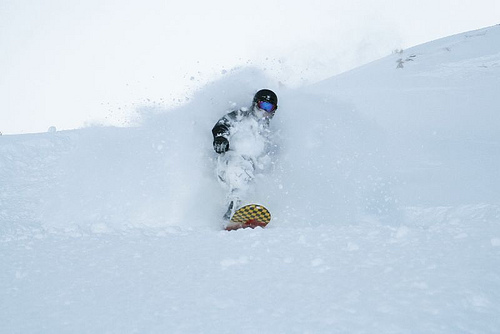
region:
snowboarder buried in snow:
[200, 70, 312, 239]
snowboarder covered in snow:
[209, 80, 288, 237]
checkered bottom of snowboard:
[226, 202, 275, 232]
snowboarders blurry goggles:
[256, 95, 276, 112]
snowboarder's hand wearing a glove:
[211, 133, 233, 158]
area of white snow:
[3, 57, 176, 332]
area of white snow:
[333, 75, 487, 279]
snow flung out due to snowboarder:
[116, 81, 206, 209]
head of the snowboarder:
[250, 82, 280, 119]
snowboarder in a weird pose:
[201, 74, 288, 234]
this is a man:
[186, 82, 301, 254]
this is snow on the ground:
[337, 228, 414, 273]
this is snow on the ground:
[158, 243, 231, 308]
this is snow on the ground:
[21, 183, 124, 295]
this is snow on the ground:
[314, 119, 385, 213]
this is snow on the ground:
[403, 203, 464, 288]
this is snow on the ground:
[46, 230, 110, 315]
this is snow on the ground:
[160, 260, 209, 320]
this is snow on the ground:
[359, 79, 421, 127]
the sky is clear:
[32, 34, 252, 79]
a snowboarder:
[199, 91, 291, 233]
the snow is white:
[9, 135, 169, 295]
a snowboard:
[234, 199, 275, 227]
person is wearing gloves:
[214, 138, 229, 157]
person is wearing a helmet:
[258, 88, 277, 99]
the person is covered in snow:
[227, 118, 267, 164]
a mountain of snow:
[419, 33, 497, 104]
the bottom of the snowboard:
[237, 208, 265, 219]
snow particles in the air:
[172, 66, 233, 96]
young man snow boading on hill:
[209, 85, 299, 240]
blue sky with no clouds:
[6, 7, 81, 58]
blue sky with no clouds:
[3, 47, 83, 105]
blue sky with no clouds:
[81, 53, 165, 81]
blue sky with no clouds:
[109, 10, 193, 56]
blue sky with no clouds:
[216, 17, 293, 39]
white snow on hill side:
[16, 147, 103, 209]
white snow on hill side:
[3, 242, 170, 331]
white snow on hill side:
[187, 268, 294, 304]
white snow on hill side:
[332, 127, 480, 259]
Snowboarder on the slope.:
[203, 84, 286, 228]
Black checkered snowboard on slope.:
[227, 200, 273, 228]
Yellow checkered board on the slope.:
[226, 203, 271, 229]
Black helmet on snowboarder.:
[248, 88, 280, 115]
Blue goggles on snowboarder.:
[255, 101, 277, 112]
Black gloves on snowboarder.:
[213, 135, 228, 155]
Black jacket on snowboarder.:
[208, 108, 273, 158]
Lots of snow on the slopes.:
[3, 20, 494, 330]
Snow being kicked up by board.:
[50, 43, 425, 241]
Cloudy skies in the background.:
[1, 3, 498, 139]